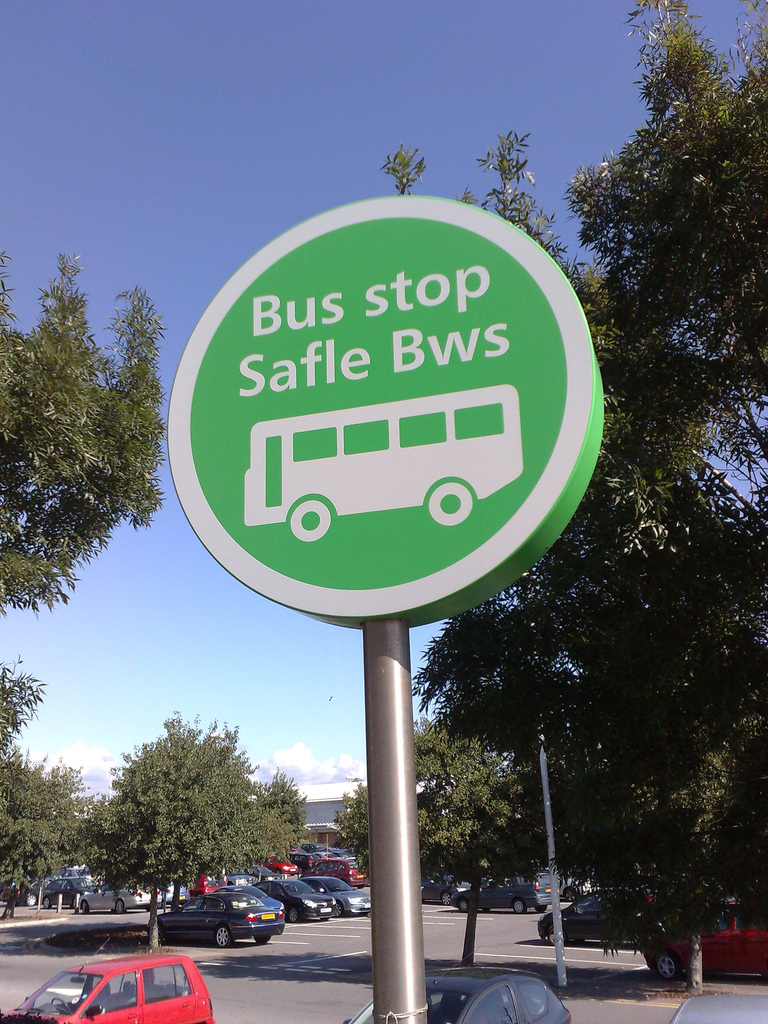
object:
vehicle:
[0, 952, 214, 1024]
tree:
[334, 720, 532, 970]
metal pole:
[362, 616, 431, 1024]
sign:
[165, 197, 605, 629]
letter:
[253, 295, 283, 338]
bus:
[245, 383, 526, 544]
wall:
[301, 803, 346, 823]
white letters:
[484, 323, 510, 358]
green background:
[188, 219, 568, 596]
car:
[156, 893, 285, 948]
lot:
[0, 896, 768, 1024]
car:
[340, 966, 568, 1024]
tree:
[79, 709, 311, 952]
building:
[256, 781, 369, 850]